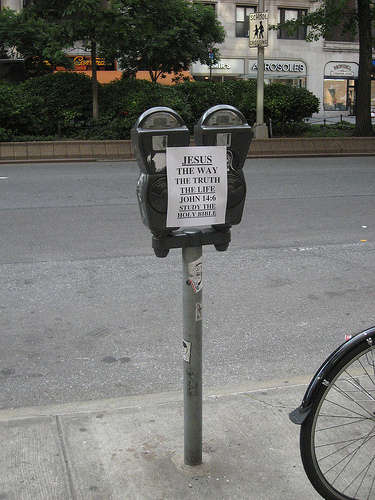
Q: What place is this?
A: It is a street.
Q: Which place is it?
A: It is a street.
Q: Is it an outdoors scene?
A: Yes, it is outdoors.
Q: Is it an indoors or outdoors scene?
A: It is outdoors.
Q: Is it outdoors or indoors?
A: It is outdoors.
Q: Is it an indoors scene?
A: No, it is outdoors.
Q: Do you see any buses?
A: No, there are no buses.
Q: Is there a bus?
A: No, there are no buses.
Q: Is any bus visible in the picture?
A: No, there are no buses.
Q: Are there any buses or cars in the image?
A: No, there are no buses or cars.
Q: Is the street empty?
A: Yes, the street is empty.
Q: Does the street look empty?
A: Yes, the street is empty.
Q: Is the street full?
A: No, the street is empty.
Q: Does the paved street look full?
A: No, the street is empty.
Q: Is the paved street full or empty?
A: The street is empty.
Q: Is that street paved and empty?
A: Yes, the street is paved and empty.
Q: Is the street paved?
A: Yes, the street is paved.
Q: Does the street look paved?
A: Yes, the street is paved.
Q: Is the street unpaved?
A: No, the street is paved.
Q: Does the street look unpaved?
A: No, the street is paved.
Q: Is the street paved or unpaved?
A: The street is paved.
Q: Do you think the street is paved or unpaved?
A: The street is paved.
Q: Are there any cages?
A: No, there are no cages.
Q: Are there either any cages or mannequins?
A: No, there are no cages or mannequins.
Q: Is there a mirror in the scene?
A: No, there are no mirrors.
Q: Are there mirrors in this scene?
A: No, there are no mirrors.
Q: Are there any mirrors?
A: No, there are no mirrors.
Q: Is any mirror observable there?
A: No, there are no mirrors.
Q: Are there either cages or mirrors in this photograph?
A: No, there are no mirrors or cages.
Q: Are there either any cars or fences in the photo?
A: No, there are no cars or fences.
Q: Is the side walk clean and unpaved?
A: No, the side walk is clean but paved.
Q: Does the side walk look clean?
A: Yes, the side walk is clean.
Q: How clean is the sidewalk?
A: The sidewalk is clean.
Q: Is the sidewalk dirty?
A: No, the sidewalk is clean.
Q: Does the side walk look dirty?
A: No, the side walk is clean.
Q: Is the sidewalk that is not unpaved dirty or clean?
A: The sidewalk is clean.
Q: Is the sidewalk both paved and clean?
A: Yes, the sidewalk is paved and clean.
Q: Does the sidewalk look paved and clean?
A: Yes, the sidewalk is paved and clean.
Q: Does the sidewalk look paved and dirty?
A: No, the sidewalk is paved but clean.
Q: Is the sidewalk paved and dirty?
A: No, the sidewalk is paved but clean.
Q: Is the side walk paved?
A: Yes, the side walk is paved.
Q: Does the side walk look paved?
A: Yes, the side walk is paved.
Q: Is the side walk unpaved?
A: No, the side walk is paved.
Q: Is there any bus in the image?
A: No, there are no buses.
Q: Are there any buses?
A: No, there are no buses.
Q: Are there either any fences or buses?
A: No, there are no buses or fences.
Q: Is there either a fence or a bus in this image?
A: No, there are no buses or fences.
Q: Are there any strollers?
A: No, there are no strollers.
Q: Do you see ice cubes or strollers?
A: No, there are no strollers or ice cubes.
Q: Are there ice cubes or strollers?
A: No, there are no strollers or ice cubes.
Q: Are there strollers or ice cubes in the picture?
A: No, there are no strollers or ice cubes.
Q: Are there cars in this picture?
A: No, there are no cars.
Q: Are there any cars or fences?
A: No, there are no cars or fences.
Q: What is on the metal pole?
A: The sign is on the pole.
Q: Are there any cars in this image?
A: No, there are no cars.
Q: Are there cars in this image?
A: No, there are no cars.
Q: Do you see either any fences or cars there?
A: No, there are no cars or fences.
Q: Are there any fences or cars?
A: No, there are no cars or fences.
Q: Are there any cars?
A: No, there are no cars.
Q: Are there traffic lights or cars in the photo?
A: No, there are no cars or traffic lights.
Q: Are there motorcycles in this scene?
A: No, there are no motorcycles.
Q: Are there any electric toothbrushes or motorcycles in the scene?
A: No, there are no motorcycles or electric toothbrushes.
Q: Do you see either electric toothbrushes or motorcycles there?
A: No, there are no motorcycles or electric toothbrushes.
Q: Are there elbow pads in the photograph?
A: No, there are no elbow pads.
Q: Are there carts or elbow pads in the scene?
A: No, there are no elbow pads or carts.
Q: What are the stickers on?
A: The stickers are on the pole.